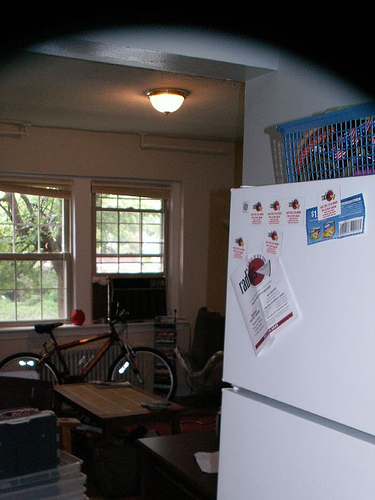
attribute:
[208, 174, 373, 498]
refrigerator — white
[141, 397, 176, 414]
remotes — black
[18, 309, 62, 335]
seat — black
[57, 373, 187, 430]
wood frame — dark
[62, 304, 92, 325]
vase — red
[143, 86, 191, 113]
light — dome shaped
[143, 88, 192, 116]
light — on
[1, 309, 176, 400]
bike — red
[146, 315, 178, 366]
dvd — stacked